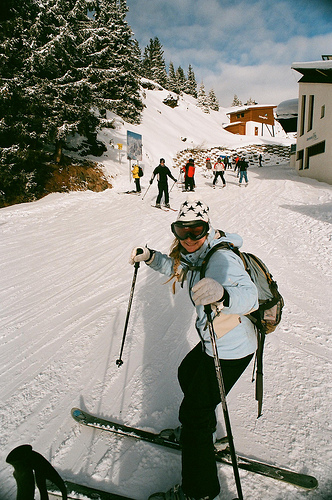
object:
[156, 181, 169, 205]
pants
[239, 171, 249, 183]
pants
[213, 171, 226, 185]
pants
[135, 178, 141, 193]
pants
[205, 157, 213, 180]
skiing people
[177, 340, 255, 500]
pants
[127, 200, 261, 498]
lady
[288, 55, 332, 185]
building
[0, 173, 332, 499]
ground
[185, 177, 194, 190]
pants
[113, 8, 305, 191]
landscape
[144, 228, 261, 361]
blue coat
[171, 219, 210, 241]
goggles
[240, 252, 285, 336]
backpack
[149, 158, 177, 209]
man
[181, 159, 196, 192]
skier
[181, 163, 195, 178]
jacket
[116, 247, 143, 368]
rod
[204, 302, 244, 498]
rod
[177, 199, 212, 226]
cap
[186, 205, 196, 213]
stars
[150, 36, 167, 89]
tree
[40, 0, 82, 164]
tree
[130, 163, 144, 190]
person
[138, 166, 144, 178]
backpack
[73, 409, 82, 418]
blue logo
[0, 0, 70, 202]
tree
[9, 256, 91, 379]
snow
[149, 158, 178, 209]
person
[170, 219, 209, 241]
ski goggles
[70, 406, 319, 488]
skis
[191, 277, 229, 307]
glove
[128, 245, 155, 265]
glove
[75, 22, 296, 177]
mountain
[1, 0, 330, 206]
background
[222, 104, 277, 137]
lodge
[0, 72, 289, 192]
hill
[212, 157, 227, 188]
people